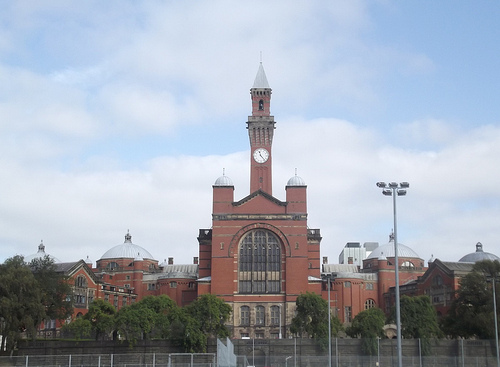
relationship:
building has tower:
[196, 50, 323, 339] [243, 48, 278, 191]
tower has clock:
[243, 48, 278, 191] [252, 147, 271, 165]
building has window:
[196, 50, 323, 339] [231, 222, 292, 298]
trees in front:
[0, 253, 499, 345] [1, 51, 499, 337]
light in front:
[317, 175, 416, 367] [1, 51, 499, 337]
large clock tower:
[196, 50, 323, 339] [243, 48, 278, 191]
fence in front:
[1, 351, 499, 366] [1, 51, 499, 337]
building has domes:
[1, 51, 499, 337] [15, 226, 498, 278]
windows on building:
[231, 222, 292, 298] [196, 50, 323, 339]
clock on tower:
[252, 147, 271, 165] [196, 50, 323, 339]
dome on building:
[95, 227, 160, 265] [1, 226, 499, 338]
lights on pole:
[317, 180, 412, 288] [317, 175, 416, 367]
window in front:
[231, 222, 292, 298] [1, 51, 499, 337]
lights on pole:
[371, 176, 415, 203] [373, 179, 414, 366]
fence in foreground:
[1, 351, 499, 366] [1, 335, 500, 366]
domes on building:
[15, 226, 498, 278] [1, 51, 499, 337]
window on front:
[231, 222, 292, 298] [1, 51, 499, 337]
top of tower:
[244, 48, 278, 94] [243, 48, 278, 191]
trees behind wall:
[0, 253, 499, 345] [1, 335, 500, 366]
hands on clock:
[256, 149, 267, 163] [252, 147, 271, 165]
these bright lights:
[371, 176, 415, 203] [317, 180, 412, 288]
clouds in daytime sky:
[1, 3, 497, 267] [1, 3, 497, 267]